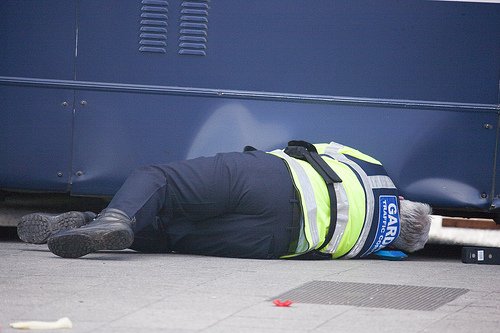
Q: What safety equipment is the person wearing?
A: Reflective vest.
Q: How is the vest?
A: Neon.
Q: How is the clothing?
A: Neon.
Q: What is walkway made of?
A: Cement.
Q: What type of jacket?
A: Security.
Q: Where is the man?
A: On ground.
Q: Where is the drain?
A: On floor.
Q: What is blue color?
A: Container.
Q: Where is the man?
A: On sidewalk.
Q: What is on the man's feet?
A: Black sneakers.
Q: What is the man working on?
A: Train.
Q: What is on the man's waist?
A: Belt.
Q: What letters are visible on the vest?
A: Gard.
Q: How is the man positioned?
A: Lying down.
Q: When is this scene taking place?
A: Daytime.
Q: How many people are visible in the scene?
A: One.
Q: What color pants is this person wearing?
A: Blue.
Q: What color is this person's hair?
A: Grey.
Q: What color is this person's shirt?
A: Blue, grey, black, neon yellow.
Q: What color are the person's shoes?
A: Black.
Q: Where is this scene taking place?
A: On a sidewalk.